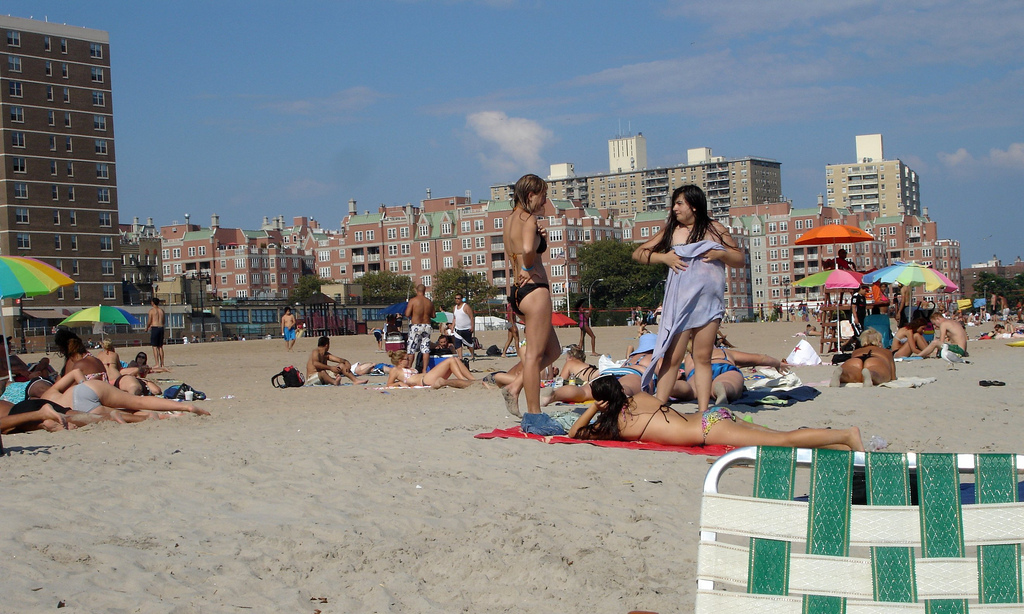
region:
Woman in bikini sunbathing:
[567, 372, 871, 453]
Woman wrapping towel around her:
[631, 183, 748, 418]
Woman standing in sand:
[494, 173, 562, 429]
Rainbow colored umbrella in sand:
[2, 249, 75, 307]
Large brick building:
[2, 14, 119, 312]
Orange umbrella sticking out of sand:
[794, 214, 872, 253]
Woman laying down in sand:
[384, 344, 477, 392]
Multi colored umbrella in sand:
[859, 257, 957, 297]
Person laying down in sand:
[836, 337, 901, 395]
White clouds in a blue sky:
[2, 0, 1018, 272]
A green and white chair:
[680, 431, 1016, 605]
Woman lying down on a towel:
[463, 354, 871, 469]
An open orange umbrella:
[781, 206, 877, 254]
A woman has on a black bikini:
[478, 156, 568, 425]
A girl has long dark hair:
[631, 169, 731, 268]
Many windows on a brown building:
[0, 7, 131, 314]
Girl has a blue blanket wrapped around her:
[615, 162, 755, 393]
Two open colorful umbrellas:
[778, 242, 971, 306]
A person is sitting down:
[904, 296, 982, 370]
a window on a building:
[37, 28, 48, 48]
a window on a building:
[48, 37, 71, 58]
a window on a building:
[72, 31, 114, 57]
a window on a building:
[92, 59, 108, 86]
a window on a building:
[61, 63, 66, 77]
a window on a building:
[7, 51, 27, 71]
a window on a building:
[0, 89, 32, 99]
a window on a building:
[38, 81, 48, 94]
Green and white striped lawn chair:
[694, 441, 1023, 612]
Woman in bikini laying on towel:
[567, 371, 869, 451]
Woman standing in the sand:
[498, 170, 559, 423]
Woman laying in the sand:
[380, 346, 479, 389]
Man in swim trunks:
[399, 277, 438, 367]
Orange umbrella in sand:
[792, 219, 873, 254]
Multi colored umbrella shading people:
[862, 254, 960, 297]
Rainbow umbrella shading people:
[1, 251, 79, 302]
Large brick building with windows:
[2, 11, 126, 316]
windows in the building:
[22, 124, 100, 189]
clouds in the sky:
[455, 89, 553, 162]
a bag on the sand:
[258, 334, 323, 417]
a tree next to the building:
[593, 225, 652, 324]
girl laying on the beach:
[836, 307, 907, 409]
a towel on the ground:
[480, 410, 554, 478]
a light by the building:
[186, 246, 222, 345]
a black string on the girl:
[645, 371, 677, 445]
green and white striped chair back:
[667, 427, 1022, 606]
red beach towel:
[490, 417, 772, 481]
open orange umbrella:
[795, 222, 872, 251]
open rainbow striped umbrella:
[55, 296, 139, 342]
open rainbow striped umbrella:
[4, 246, 74, 313]